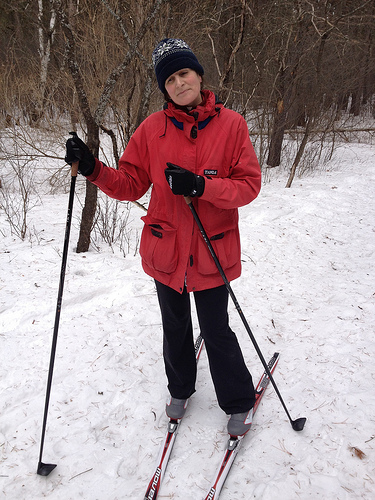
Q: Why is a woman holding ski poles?
A: To ski.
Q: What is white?
A: Snow.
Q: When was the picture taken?
A: Daytime.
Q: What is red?
A: Woman's jacket.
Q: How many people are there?
A: One.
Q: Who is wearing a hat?
A: Skier.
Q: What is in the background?
A: Trees.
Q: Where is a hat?
A: On woman's head.